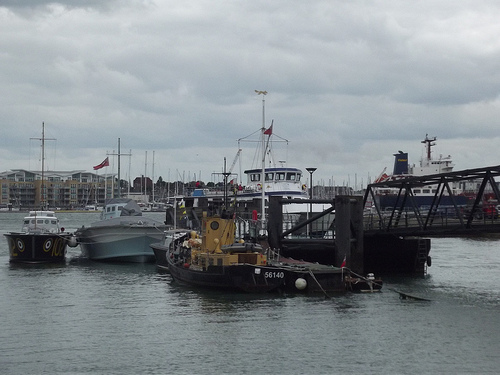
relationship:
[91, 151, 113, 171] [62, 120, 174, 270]
flag flying on boat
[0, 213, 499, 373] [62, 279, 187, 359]
water with ripples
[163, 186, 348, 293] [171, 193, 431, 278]
boat at dock